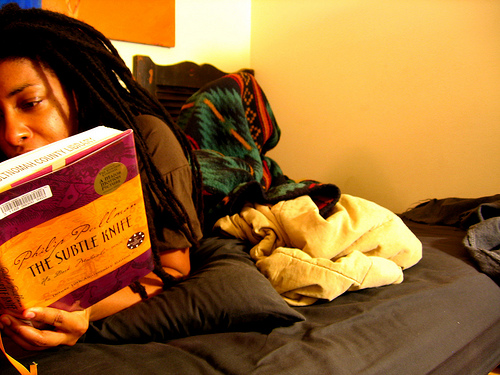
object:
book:
[0, 111, 162, 346]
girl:
[0, 4, 211, 369]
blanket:
[176, 62, 345, 219]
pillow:
[51, 226, 310, 355]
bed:
[0, 245, 497, 374]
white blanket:
[206, 187, 428, 312]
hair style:
[1, 2, 208, 303]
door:
[124, 44, 258, 105]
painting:
[21, 0, 190, 57]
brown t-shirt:
[105, 111, 213, 251]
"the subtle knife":
[22, 211, 141, 282]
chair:
[123, 46, 272, 133]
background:
[67, 6, 493, 93]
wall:
[261, 8, 494, 197]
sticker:
[88, 160, 131, 198]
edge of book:
[2, 110, 127, 202]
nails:
[1, 297, 30, 320]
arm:
[71, 117, 210, 349]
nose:
[1, 106, 36, 150]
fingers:
[17, 307, 85, 328]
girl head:
[0, 4, 129, 186]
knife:
[97, 210, 139, 245]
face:
[0, 45, 81, 163]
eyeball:
[20, 96, 42, 111]